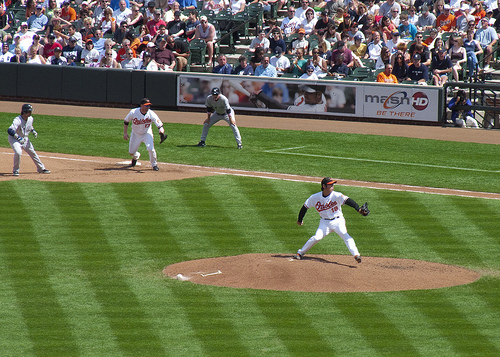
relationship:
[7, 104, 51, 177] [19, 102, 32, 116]
baseball player wearing helmet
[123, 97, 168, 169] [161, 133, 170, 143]
baseball player wearing glove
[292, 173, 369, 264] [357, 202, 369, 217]
baseball player wearing glove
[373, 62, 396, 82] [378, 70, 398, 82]
man wearing orange shirt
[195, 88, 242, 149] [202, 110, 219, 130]
baseball player resting hand thigh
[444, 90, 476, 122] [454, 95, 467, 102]
man holding camera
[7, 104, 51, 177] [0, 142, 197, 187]
baseball player taking lead first base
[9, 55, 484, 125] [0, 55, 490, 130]
wall dividing field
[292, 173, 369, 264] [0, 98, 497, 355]
baseball player on baseball field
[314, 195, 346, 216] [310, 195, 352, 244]
name on uniform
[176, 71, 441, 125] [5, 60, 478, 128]
sign on wall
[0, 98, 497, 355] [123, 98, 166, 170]
baseball field with baseball player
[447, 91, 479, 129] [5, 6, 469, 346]
man taking picture